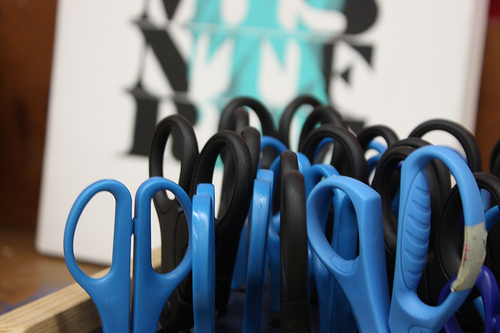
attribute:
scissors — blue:
[55, 173, 197, 329]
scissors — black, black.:
[273, 149, 313, 332]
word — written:
[124, 19, 382, 109]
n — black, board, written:
[129, 22, 197, 88]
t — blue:
[202, 29, 292, 104]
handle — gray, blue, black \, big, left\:
[452, 223, 490, 292]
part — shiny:
[190, 209, 214, 265]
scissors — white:
[451, 223, 482, 289]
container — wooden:
[3, 248, 164, 332]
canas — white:
[389, 7, 484, 141]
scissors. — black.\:
[58, 87, 495, 329]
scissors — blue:
[49, 176, 243, 315]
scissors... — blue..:
[157, 81, 321, 305]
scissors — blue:
[61, 177, 202, 332]